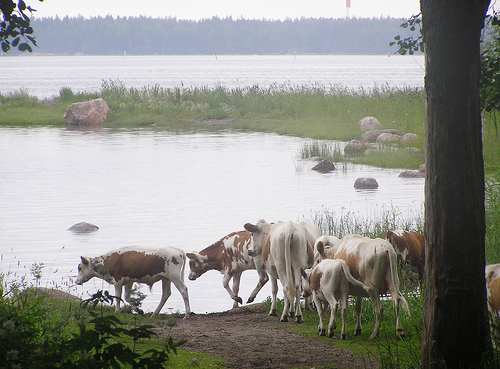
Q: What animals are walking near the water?
A: Cows.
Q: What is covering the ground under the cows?
A: Grass.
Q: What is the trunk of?
A: A tree.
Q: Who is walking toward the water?
A: Cows.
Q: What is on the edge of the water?
A: A boulder.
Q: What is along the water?
A: Trees.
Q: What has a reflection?
A: The lake.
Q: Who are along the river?
A: Cows.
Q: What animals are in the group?
A: Cows.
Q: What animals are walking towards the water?
A: Cows.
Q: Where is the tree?
A: Ground.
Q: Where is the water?
A: Near cow.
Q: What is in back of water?
A: Grass.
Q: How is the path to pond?
A: Dirt.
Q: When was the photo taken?
A: Daytime.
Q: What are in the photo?
A: Cattle.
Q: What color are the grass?
A: Green.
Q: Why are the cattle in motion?
A: To drink water.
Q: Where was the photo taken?
A: A watering hole.